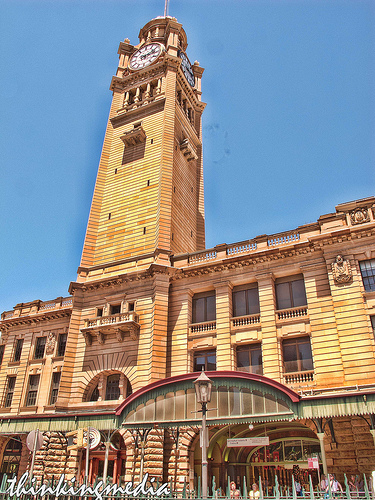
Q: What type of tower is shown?
A: A clock tower.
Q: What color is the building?
A: Tan / brown.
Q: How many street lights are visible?
A: One.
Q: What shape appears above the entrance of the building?
A: An arc.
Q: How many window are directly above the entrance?
A: Six.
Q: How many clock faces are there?
A: Two.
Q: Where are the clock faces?
A: On the front and right side of the clock tower.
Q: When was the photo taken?
A: During the day.